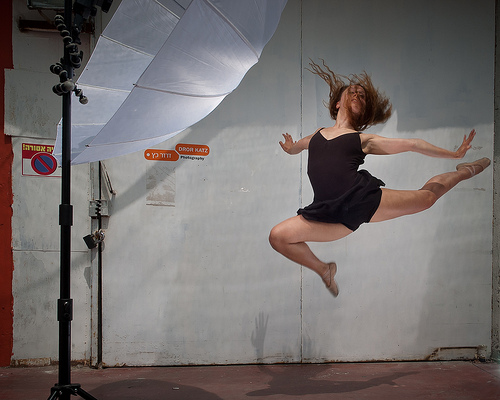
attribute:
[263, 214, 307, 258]
knee — bent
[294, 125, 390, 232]
dress — black, stretchy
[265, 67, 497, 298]
lady — light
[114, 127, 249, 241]
signs — red, black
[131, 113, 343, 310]
wall — white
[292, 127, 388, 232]
outfit — black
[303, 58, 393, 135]
hair — long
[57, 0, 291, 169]
umbrella — white, photography light umbrella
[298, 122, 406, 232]
dress — black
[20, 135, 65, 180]
sign — red, blue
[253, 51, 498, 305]
lady — airborne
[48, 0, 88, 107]
electric wires — electrical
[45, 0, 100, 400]
light pole — gray, black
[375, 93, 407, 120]
hair — wavy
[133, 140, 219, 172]
hebrew — orange-and-white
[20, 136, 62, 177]
sign — red, yellow, blue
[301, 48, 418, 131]
long hair — brown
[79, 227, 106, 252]
padlock — black, silver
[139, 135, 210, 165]
signs — Hebrew